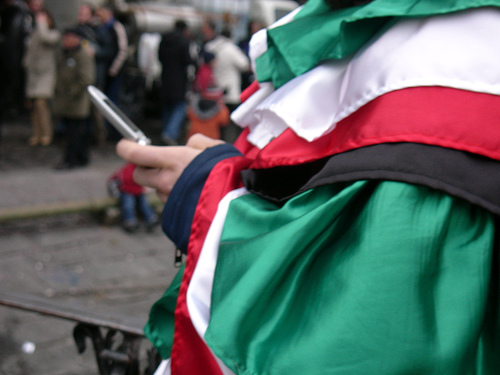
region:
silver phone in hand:
[84, 83, 153, 147]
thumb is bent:
[188, 132, 222, 149]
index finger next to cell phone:
[114, 140, 187, 162]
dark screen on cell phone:
[103, 98, 141, 135]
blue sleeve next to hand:
[157, 142, 234, 253]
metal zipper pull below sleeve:
[172, 246, 184, 269]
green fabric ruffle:
[250, 2, 499, 87]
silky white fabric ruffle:
[230, 15, 499, 148]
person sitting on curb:
[107, 158, 167, 231]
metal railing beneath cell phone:
[2, 297, 147, 338]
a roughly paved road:
[0, 224, 197, 373]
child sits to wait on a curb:
[106, 162, 158, 234]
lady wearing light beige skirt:
[17, 10, 61, 154]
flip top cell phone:
[83, 82, 158, 147]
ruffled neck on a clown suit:
[228, 0, 499, 247]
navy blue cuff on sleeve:
[162, 137, 245, 247]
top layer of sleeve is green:
[193, 177, 493, 374]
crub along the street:
[3, 187, 113, 245]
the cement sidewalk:
[2, 124, 191, 216]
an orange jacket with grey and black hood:
[183, 86, 233, 149]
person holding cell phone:
[5, 3, 492, 372]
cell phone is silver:
[77, 81, 159, 158]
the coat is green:
[53, 2, 498, 369]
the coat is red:
[135, 4, 475, 364]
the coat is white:
[62, 4, 493, 361]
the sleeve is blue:
[156, 130, 241, 257]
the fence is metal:
[2, 279, 173, 368]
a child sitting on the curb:
[102, 127, 162, 237]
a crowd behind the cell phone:
[2, 0, 268, 151]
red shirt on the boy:
[96, 161, 166, 198]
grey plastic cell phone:
[82, 76, 167, 151]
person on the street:
[143, 3, 198, 151]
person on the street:
[49, 25, 96, 182]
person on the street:
[15, 1, 62, 161]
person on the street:
[200, 17, 257, 115]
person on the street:
[183, 40, 225, 121]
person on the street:
[173, 75, 240, 164]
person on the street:
[98, 153, 165, 241]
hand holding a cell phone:
[68, 52, 228, 249]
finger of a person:
[108, 134, 182, 167]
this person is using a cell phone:
[25, 9, 467, 295]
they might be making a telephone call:
[69, 78, 247, 214]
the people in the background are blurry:
[15, 3, 247, 222]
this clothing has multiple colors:
[155, 81, 484, 359]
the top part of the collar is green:
[263, 1, 499, 50]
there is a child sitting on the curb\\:
[96, 151, 171, 234]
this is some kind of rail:
[1, 282, 168, 363]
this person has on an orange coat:
[185, 81, 237, 138]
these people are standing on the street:
[8, 149, 200, 366]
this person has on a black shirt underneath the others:
[138, 138, 244, 239]